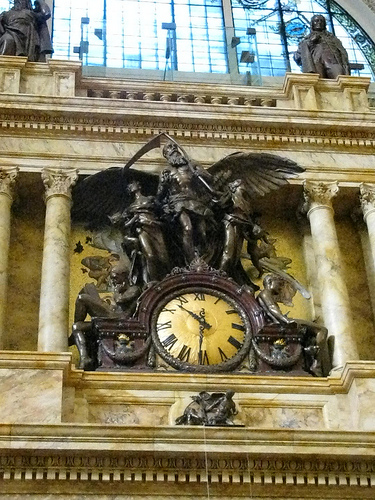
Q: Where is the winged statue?
A: Above the clock.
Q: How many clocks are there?
A: One.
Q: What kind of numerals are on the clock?
A: Roman.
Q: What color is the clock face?
A: Yellow.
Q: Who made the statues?
A: Sculptor.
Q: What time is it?
A: 10:30.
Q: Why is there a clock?
A: Tell time.